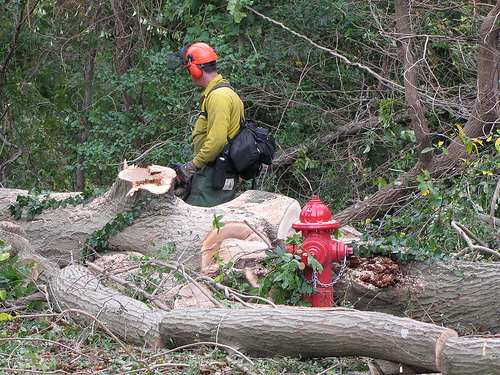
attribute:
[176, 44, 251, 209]
man — cutting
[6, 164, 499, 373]
tree — fallen, chopped, cut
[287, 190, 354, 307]
fire hydrant — red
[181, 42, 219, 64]
helmet — orange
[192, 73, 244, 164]
jacket — yellow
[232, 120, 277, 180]
backpack — black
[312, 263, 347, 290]
chain — metal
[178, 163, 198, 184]
glove — gray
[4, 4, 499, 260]
brush — thick, green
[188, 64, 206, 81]
ear muffs — orange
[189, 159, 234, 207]
pant — black